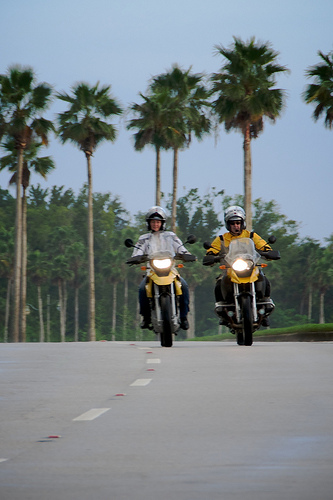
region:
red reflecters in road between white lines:
[44, 421, 59, 449]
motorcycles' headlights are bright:
[133, 252, 270, 282]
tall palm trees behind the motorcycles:
[0, 51, 330, 146]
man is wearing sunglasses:
[218, 207, 255, 237]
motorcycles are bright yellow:
[138, 267, 306, 294]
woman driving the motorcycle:
[133, 206, 173, 338]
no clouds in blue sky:
[17, 5, 243, 60]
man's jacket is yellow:
[212, 222, 288, 281]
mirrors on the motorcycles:
[110, 233, 300, 244]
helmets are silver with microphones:
[142, 199, 248, 225]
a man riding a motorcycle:
[201, 205, 279, 345]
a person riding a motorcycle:
[124, 207, 196, 346]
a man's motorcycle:
[202, 240, 280, 347]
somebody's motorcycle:
[125, 236, 195, 346]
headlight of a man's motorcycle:
[231, 259, 254, 274]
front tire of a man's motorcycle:
[235, 291, 256, 346]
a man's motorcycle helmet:
[221, 205, 245, 221]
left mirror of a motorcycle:
[176, 235, 196, 253]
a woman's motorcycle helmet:
[145, 205, 169, 220]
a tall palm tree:
[58, 84, 124, 339]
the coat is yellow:
[204, 217, 268, 265]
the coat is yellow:
[217, 210, 284, 285]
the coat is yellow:
[170, 196, 287, 347]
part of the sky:
[100, 1, 146, 44]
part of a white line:
[89, 397, 112, 420]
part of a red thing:
[46, 427, 64, 440]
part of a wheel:
[233, 309, 257, 346]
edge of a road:
[280, 326, 306, 339]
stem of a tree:
[81, 300, 98, 326]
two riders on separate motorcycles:
[112, 180, 280, 352]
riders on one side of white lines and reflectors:
[26, 321, 159, 446]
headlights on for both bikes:
[129, 249, 268, 278]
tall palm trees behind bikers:
[14, 11, 284, 330]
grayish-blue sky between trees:
[21, 134, 203, 196]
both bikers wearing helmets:
[134, 200, 253, 236]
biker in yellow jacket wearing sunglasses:
[203, 206, 270, 260]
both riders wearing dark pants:
[130, 267, 288, 339]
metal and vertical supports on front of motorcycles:
[142, 272, 269, 326]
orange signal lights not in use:
[135, 251, 276, 274]